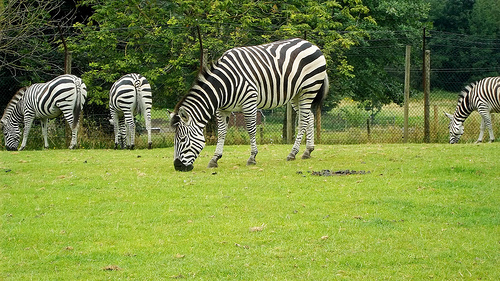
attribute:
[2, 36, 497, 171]
zebras — black, white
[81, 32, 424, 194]
zebras — white, black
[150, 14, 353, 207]
zebra — striped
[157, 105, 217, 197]
head — bent, down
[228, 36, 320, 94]
stripes — black, white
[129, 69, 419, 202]
zebra — black, white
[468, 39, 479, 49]
leaf — green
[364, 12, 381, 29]
leaf — green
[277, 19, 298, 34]
leaf — green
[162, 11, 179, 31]
leaf — green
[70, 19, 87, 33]
leaf — green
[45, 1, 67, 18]
branch — green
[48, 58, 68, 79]
branch — green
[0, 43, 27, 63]
branch — green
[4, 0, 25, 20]
branch — green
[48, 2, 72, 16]
branch — green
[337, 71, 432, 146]
fence — wire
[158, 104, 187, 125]
ears — large, upright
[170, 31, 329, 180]
zebra — black, white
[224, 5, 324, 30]
leaves — light green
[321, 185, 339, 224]
grass — bright green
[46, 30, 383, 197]
zebras — black, white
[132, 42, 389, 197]
zebra — white, black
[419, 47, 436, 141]
pole — concrete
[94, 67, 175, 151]
zebra — white, black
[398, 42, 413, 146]
post — thin, wooden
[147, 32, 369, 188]
zebra — white, black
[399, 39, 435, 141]
pole — wooden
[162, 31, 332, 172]
zebra — black, white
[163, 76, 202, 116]
manes — white, black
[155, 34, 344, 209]
zebra — striped